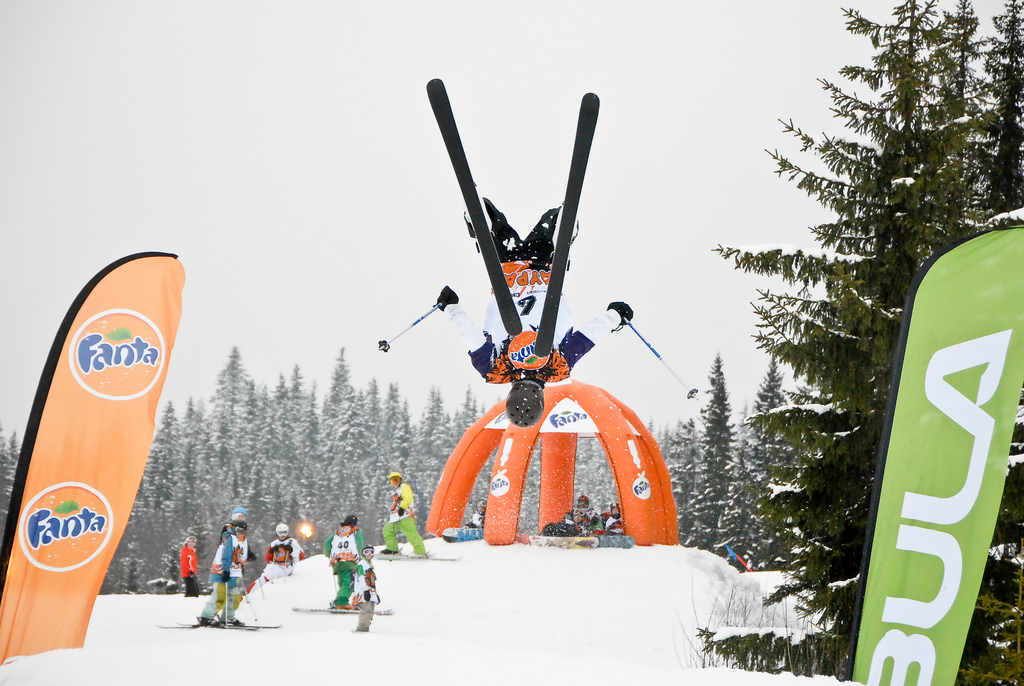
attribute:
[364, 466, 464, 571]
person — playing